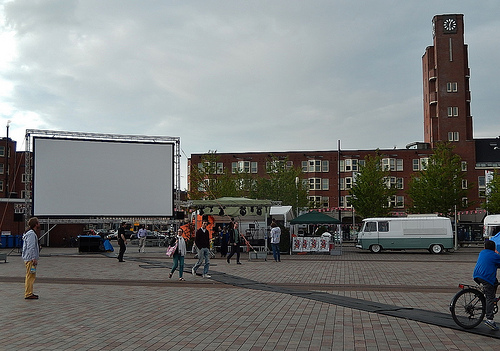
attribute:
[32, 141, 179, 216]
screen — projection, large, white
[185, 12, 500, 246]
building — brick, red, large, brown, tower, tall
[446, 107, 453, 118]
window — white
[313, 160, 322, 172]
window — white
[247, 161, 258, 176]
window — white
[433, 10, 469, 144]
tower — clock, tall, red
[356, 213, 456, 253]
van — grey, white, blue, parked, green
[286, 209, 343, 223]
tent — green, dark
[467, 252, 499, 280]
shirt — blue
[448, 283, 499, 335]
bicycle — black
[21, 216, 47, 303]
man — walking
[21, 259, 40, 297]
pants — yellow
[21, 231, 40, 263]
shirt — grey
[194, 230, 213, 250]
sweater — black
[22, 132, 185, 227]
billboard — bare, white, large, black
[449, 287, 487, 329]
wheel — black, back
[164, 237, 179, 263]
bag — pink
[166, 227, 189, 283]
woman — walking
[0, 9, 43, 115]
cloud — dark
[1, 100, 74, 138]
cloud — dark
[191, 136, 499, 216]
cluster — trees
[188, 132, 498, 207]
trees — green, tall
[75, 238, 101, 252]
table — black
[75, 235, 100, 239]
top — blue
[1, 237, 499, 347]
street — brick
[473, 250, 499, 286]
jacket — blue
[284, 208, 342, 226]
awning — green, tent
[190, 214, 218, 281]
person — walking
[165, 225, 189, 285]
person — walking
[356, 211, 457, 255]
bus — green, white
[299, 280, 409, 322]
mat — black, rubber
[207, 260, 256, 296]
mat — black, rubber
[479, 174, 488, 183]
window — white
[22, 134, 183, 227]
frame — metal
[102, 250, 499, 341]
walkway — black